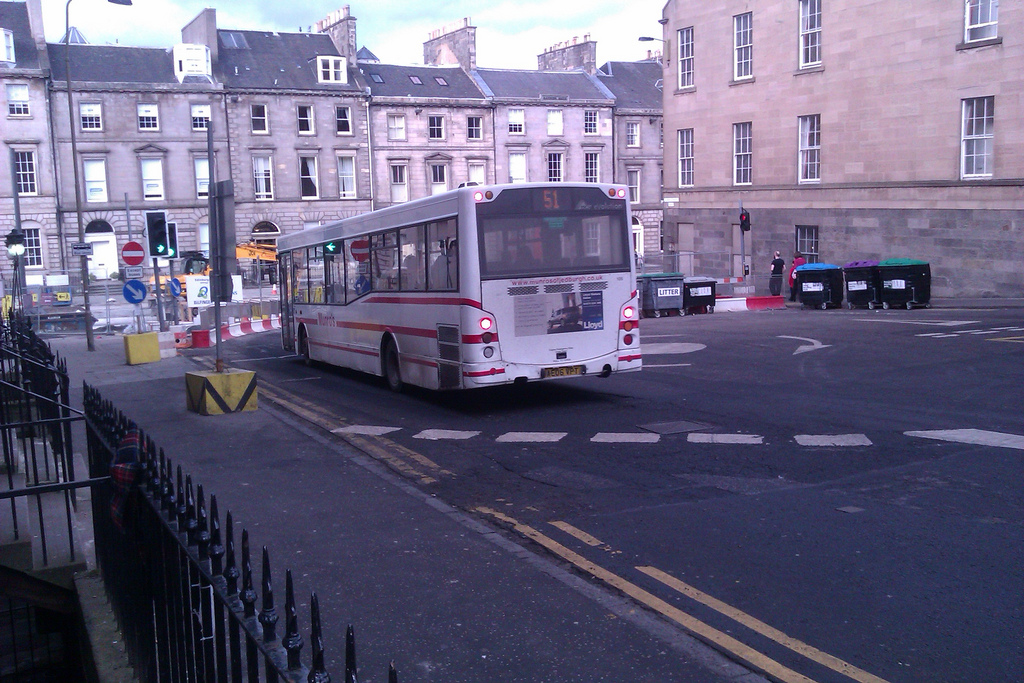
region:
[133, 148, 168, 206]
window on the building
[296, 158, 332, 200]
window on the building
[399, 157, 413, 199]
window on the building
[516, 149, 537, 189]
window on the building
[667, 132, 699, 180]
window on the building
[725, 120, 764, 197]
window on the building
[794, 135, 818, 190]
window on the building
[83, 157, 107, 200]
building has a window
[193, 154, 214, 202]
building has a window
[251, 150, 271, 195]
building has a window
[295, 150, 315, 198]
building has a window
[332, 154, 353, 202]
building has a window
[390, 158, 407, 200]
building has a window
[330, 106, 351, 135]
building has a window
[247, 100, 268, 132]
building has a window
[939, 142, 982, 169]
window on the building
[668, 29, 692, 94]
window on the building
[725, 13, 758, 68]
window on the building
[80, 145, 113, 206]
window on the building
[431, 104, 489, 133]
window on the building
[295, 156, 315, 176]
a window on the building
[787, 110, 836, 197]
a window on the building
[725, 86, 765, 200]
a window on the building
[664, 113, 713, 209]
a window on the building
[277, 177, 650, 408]
bus travels down street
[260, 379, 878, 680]
lines are yellow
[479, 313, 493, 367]
headlight belongs to bus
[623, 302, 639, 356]
headlight belongs to bus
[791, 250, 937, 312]
trashcans next to street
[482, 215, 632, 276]
rearview window belongs to bus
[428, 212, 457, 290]
window belongs to bus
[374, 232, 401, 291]
window belongs to bus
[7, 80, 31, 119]
window on front of house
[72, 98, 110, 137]
window on front of house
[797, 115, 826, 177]
A window on a building.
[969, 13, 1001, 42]
A window on a building.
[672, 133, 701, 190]
A window on a building.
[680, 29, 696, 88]
A window on a building.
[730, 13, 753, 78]
A window on a building.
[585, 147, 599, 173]
A window on a building.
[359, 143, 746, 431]
back of the bus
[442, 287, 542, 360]
light on back of bus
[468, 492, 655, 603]
yellow lines on street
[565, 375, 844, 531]
street behind the bus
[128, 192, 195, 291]
green light on pole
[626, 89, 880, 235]
windows on the building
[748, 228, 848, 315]
people next to the building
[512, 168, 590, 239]
number on back of bus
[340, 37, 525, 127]
roof of the building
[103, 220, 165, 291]
red and white sign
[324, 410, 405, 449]
white square on street